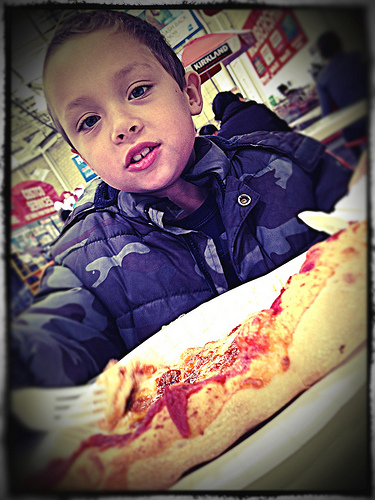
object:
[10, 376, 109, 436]
fork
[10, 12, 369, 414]
boy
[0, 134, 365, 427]
jacket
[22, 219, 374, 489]
pizza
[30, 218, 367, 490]
plate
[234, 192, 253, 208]
button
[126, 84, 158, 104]
eye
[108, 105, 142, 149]
nose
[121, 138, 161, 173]
mouth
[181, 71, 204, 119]
ear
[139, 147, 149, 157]
teeth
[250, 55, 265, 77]
advertisement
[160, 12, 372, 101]
wall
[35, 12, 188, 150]
hair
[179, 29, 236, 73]
umbrella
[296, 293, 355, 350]
crust